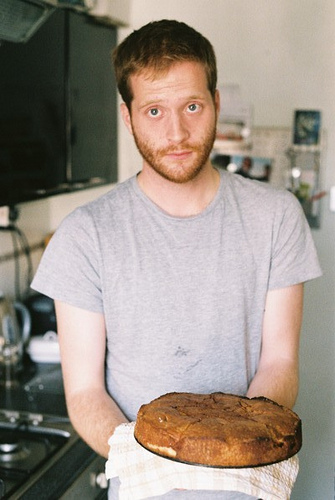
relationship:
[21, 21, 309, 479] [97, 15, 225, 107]
man with hair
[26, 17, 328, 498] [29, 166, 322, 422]
man in shirt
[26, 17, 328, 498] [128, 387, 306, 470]
man holding pastry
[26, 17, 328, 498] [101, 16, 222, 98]
man has hair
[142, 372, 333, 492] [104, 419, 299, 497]
bread on cloth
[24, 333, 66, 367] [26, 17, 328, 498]
butter container on man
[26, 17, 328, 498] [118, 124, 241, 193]
man with a beard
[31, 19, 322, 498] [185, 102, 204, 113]
person with eye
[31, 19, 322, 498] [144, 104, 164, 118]
person with eye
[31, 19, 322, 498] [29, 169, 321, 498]
person wearing t-shirt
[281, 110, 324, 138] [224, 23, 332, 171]
picture on wall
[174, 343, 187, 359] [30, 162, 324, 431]
stain on t shirt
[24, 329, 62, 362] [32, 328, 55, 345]
container has lid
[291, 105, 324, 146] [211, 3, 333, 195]
picture on wall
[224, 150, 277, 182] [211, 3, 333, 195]
picture on wall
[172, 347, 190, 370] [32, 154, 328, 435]
stain on shirt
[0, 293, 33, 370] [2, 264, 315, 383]
blender on counter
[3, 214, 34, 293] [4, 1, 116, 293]
wires on wall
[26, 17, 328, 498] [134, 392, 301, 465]
man holding cake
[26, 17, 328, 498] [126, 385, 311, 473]
man holding cake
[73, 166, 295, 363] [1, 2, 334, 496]
man in kitchen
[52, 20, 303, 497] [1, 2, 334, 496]
man in kitchen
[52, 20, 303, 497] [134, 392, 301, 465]
man with cake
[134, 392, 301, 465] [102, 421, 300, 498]
cake on towel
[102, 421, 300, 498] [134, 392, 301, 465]
towel on cake